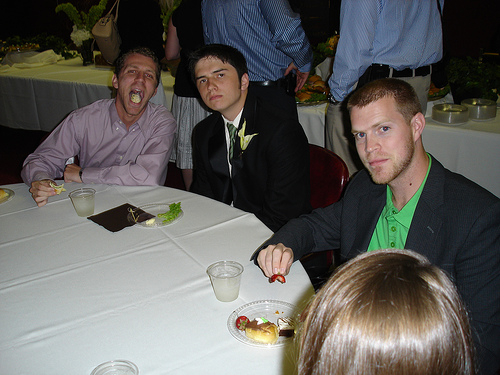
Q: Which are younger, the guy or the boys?
A: The boys are younger than the guy.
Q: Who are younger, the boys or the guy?
A: The boys are younger than the guy.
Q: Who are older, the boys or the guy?
A: The guy are older than the boys.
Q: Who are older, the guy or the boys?
A: The guy are older than the boys.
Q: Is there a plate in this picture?
A: Yes, there is a plate.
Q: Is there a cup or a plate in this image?
A: Yes, there is a plate.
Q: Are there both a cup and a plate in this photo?
A: Yes, there are both a plate and a cup.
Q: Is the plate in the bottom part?
A: Yes, the plate is in the bottom of the image.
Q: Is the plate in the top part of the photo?
A: No, the plate is in the bottom of the image.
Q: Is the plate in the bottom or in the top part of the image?
A: The plate is in the bottom of the image.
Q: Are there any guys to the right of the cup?
A: Yes, there is a guy to the right of the cup.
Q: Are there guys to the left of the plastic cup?
A: No, the guy is to the right of the cup.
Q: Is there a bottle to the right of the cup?
A: No, there is a guy to the right of the cup.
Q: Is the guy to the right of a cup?
A: Yes, the guy is to the right of a cup.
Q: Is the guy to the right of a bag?
A: No, the guy is to the right of a cup.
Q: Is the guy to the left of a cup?
A: No, the guy is to the right of a cup.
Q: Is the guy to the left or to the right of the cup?
A: The guy is to the right of the cup.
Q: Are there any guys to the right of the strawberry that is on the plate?
A: Yes, there is a guy to the right of the strawberry.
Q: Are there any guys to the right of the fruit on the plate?
A: Yes, there is a guy to the right of the strawberry.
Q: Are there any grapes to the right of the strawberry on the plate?
A: No, there is a guy to the right of the strawberry.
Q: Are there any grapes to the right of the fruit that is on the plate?
A: No, there is a guy to the right of the strawberry.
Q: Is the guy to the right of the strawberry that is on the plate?
A: Yes, the guy is to the right of the strawberry.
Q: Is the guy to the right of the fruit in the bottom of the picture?
A: Yes, the guy is to the right of the strawberry.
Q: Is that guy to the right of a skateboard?
A: No, the guy is to the right of the strawberry.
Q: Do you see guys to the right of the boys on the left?
A: Yes, there is a guy to the right of the boys.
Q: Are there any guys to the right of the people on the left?
A: Yes, there is a guy to the right of the boys.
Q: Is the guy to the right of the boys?
A: Yes, the guy is to the right of the boys.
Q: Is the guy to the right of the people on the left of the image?
A: Yes, the guy is to the right of the boys.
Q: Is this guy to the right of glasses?
A: No, the guy is to the right of the boys.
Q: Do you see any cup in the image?
A: Yes, there is a cup.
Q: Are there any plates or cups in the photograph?
A: Yes, there is a cup.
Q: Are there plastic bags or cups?
A: Yes, there is a plastic cup.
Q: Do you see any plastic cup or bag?
A: Yes, there is a plastic cup.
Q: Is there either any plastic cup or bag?
A: Yes, there is a plastic cup.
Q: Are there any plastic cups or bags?
A: Yes, there is a plastic cup.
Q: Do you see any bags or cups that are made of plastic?
A: Yes, the cup is made of plastic.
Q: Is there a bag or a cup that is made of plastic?
A: Yes, the cup is made of plastic.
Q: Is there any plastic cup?
A: Yes, there is a cup that is made of plastic.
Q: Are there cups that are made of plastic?
A: Yes, there is a cup that is made of plastic.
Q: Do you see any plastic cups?
A: Yes, there is a cup that is made of plastic.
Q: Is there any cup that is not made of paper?
A: Yes, there is a cup that is made of plastic.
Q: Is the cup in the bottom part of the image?
A: Yes, the cup is in the bottom of the image.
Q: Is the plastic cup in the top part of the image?
A: No, the cup is in the bottom of the image.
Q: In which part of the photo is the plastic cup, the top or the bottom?
A: The cup is in the bottom of the image.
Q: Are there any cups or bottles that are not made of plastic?
A: No, there is a cup but it is made of plastic.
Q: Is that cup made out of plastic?
A: Yes, the cup is made of plastic.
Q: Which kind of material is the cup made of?
A: The cup is made of plastic.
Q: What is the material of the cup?
A: The cup is made of plastic.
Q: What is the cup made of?
A: The cup is made of plastic.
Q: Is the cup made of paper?
A: No, the cup is made of plastic.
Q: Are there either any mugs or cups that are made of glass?
A: No, there is a cup but it is made of plastic.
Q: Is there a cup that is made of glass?
A: No, there is a cup but it is made of plastic.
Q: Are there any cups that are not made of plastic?
A: No, there is a cup but it is made of plastic.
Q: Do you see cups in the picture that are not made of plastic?
A: No, there is a cup but it is made of plastic.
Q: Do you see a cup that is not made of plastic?
A: No, there is a cup but it is made of plastic.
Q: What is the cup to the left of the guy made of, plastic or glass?
A: The cup is made of plastic.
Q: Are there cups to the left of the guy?
A: Yes, there is a cup to the left of the guy.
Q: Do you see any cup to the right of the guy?
A: No, the cup is to the left of the guy.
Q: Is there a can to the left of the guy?
A: No, there is a cup to the left of the guy.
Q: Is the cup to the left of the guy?
A: Yes, the cup is to the left of the guy.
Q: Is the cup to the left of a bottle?
A: No, the cup is to the left of the guy.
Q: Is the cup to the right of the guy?
A: No, the cup is to the left of the guy.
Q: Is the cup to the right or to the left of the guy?
A: The cup is to the left of the guy.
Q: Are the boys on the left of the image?
A: Yes, the boys are on the left of the image.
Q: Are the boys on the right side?
A: No, the boys are on the left of the image.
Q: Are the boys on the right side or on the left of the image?
A: The boys are on the left of the image.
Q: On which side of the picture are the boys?
A: The boys are on the left of the image.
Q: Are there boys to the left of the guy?
A: Yes, there are boys to the left of the guy.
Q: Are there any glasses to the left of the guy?
A: No, there are boys to the left of the guy.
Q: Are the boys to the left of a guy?
A: Yes, the boys are to the left of a guy.